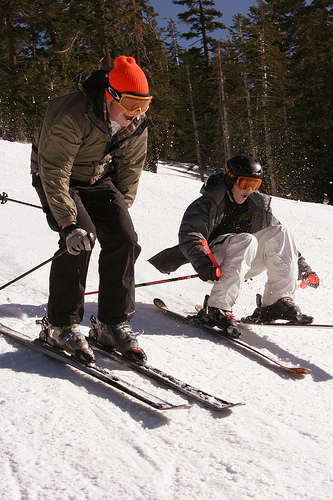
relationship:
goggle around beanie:
[106, 83, 153, 114] [105, 56, 149, 98]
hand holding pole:
[66, 228, 93, 255] [1, 232, 95, 291]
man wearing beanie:
[29, 56, 151, 367] [105, 56, 149, 98]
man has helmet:
[178, 155, 318, 338] [223, 156, 264, 203]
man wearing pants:
[178, 155, 318, 338] [206, 223, 300, 311]